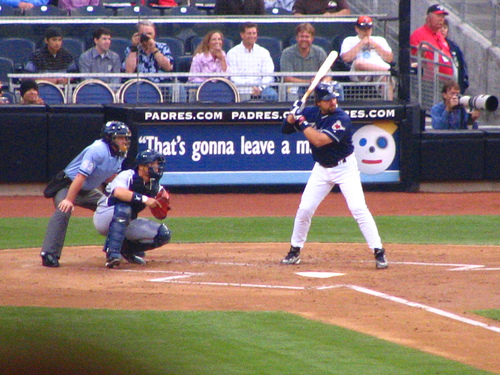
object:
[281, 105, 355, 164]
jersey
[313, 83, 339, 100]
helmet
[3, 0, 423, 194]
stands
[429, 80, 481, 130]
man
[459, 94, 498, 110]
large/telephoto lens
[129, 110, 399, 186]
advertisement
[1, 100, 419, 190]
wall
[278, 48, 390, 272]
baseball batter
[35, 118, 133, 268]
referee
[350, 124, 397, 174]
clown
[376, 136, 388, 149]
black eye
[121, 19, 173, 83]
man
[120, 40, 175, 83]
blue/white shirt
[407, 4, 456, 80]
shirt/cap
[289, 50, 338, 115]
baseball bat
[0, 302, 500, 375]
area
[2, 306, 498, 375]
green grass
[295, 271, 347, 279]
home plate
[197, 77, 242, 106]
seat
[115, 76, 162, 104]
seat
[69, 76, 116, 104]
seat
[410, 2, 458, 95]
man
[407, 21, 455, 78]
shirt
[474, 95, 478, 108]
lense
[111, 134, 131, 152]
face mask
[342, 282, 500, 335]
line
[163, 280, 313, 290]
line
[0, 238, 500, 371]
dirt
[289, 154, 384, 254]
pants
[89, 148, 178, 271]
catcher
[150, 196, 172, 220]
glove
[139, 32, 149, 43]
camera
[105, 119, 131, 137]
helmet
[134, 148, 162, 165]
helmet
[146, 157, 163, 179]
mask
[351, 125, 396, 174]
face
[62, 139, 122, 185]
shirt